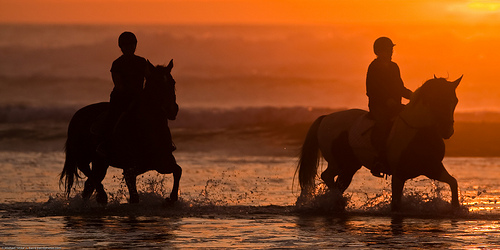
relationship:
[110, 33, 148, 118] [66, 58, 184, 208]
person on horse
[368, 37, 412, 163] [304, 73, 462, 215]
person on horse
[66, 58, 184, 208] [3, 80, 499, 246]
horse in water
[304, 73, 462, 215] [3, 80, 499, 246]
horse in water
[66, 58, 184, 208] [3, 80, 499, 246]
horse walking in water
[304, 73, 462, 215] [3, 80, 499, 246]
horse walking in water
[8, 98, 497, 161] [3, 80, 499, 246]
wave in water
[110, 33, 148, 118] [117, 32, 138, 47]
person wearing helmet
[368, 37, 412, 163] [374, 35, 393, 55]
person wearing helmet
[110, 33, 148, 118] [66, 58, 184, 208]
person riding horse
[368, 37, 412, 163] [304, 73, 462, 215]
person riding horse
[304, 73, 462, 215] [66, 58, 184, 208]
horse in front of horse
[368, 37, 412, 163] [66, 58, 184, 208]
person riding horse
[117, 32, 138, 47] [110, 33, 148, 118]
helmet on person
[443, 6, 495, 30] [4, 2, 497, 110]
sun in sky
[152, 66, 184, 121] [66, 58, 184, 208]
face of horse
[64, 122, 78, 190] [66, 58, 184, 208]
tail of horse